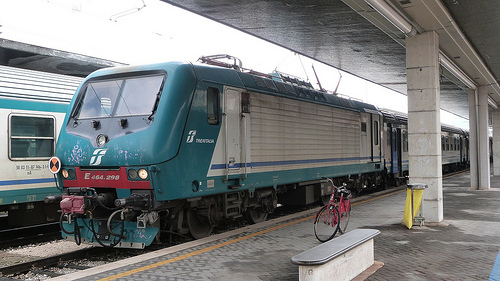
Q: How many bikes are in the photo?
A: 1.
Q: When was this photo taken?
A: Daytime.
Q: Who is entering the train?
A: Noone.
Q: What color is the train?
A: Blue and grey.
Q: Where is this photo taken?
A: Train station.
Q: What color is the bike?
A: Red.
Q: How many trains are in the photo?
A: 2.